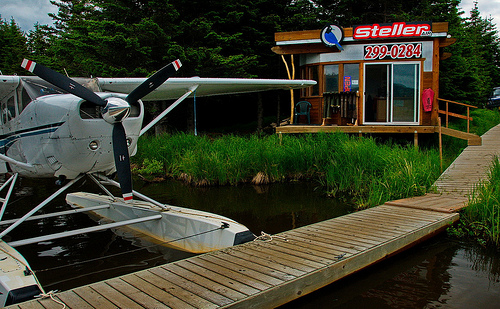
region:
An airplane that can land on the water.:
[6, 36, 309, 299]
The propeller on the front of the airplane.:
[20, 42, 190, 207]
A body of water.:
[5, 187, 490, 302]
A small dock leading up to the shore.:
[23, 150, 499, 305]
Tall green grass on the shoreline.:
[147, 120, 494, 205]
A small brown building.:
[264, 25, 478, 145]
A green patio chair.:
[291, 95, 314, 126]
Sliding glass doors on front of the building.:
[359, 58, 422, 128]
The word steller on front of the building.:
[353, 18, 432, 39]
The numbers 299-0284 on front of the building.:
[358, 43, 424, 65]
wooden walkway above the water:
[269, 208, 426, 273]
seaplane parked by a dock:
[1, 63, 313, 290]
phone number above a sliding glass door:
[361, 44, 423, 61]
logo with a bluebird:
[321, 24, 347, 53]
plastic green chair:
[295, 100, 312, 126]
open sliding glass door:
[363, 60, 421, 123]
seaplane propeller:
[16, 46, 185, 203]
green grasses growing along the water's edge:
[167, 135, 370, 205]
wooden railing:
[438, 98, 482, 134]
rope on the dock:
[251, 227, 283, 243]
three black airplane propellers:
[0, 50, 196, 207]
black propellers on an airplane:
[4, 45, 196, 198]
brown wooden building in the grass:
[270, 20, 472, 152]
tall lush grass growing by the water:
[163, 126, 435, 214]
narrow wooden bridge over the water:
[6, 193, 455, 306]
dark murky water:
[205, 178, 335, 230]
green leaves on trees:
[35, 0, 290, 84]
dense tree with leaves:
[35, 2, 294, 79]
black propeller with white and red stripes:
[10, 46, 119, 116]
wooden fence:
[426, 85, 486, 148]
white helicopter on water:
[9, 62, 256, 258]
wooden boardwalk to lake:
[110, 198, 432, 278]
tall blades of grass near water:
[194, 140, 393, 175]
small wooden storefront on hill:
[276, 10, 464, 157]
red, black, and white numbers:
[356, 36, 423, 84]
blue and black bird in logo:
[311, 28, 351, 55]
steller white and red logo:
[354, 18, 448, 46]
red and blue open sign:
[340, 73, 362, 99]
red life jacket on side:
[417, 82, 445, 119]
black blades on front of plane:
[17, 58, 188, 210]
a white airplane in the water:
[0, 55, 307, 257]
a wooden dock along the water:
[20, 200, 460, 307]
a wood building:
[269, 20, 447, 135]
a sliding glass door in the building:
[363, 62, 418, 124]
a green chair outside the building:
[294, 100, 311, 125]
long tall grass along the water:
[163, 129, 409, 204]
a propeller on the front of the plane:
[16, 57, 184, 204]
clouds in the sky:
[12, 4, 50, 16]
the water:
[238, 183, 313, 220]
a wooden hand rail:
[436, 95, 476, 137]